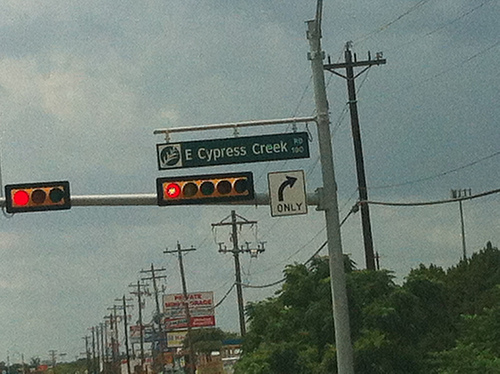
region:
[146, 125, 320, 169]
green and white street sign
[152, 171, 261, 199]
yellow traffic signal turned red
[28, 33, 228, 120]
overcast cloudy sky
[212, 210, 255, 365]
tall wooden telephone pole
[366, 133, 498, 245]
long utility lines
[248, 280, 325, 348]
green leaves on trees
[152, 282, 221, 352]
sign for self storage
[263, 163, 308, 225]
arrow pointing right on sign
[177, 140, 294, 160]
sign for E Cypress Creek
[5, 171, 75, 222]
traffic signal fixed to pole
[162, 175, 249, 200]
street light on red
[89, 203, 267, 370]
row of telephone poles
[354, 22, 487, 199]
group of telephone lines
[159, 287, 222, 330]
red and white billboard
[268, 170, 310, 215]
white sign with a black arrow on it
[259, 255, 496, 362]
group of trees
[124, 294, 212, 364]
group of billboards along the road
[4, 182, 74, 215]
three lights in a row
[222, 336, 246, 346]
blue top of a building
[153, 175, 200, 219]
Red light illuminated on traffic light.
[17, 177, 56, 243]
Red light illuminated on traffic signal.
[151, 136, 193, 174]
White leaf on green sign.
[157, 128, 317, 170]
Green sign attached to pole.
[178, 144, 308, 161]
White lettering on green sign.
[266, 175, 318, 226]
White ans black sign attached to pole.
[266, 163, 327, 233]
Black arrow on white sign.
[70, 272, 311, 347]
Many telephone poles in a row.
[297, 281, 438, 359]
Green leaves on trees.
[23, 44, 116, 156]
White clouds in sky.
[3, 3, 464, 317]
Picture taken on a cloudy day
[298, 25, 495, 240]
Power pole with many wires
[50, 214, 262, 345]
A long line of power poles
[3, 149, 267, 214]
Traffic signals are lit red at this time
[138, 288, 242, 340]
White billboard with red lettering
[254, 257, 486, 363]
Trees next to the roadway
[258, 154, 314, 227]
White sign with black arrow and lettering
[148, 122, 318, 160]
Green street sign with white lettering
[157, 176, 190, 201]
Red light on traffic signal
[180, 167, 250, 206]
Unlit lights on traffic signal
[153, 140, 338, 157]
Green sign attached to pole.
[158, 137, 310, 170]
White lettering on green sign.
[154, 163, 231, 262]
Red light illuminated on traffic light.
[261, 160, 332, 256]
Black and white sign attached to pole.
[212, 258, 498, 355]
Green leaves on tree branches.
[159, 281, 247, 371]
Large white sign in distance.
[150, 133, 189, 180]
White leaf on sign.